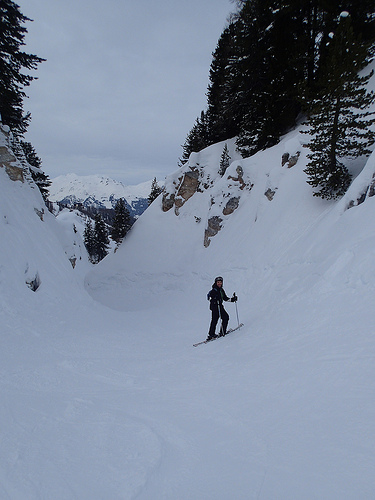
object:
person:
[207, 277, 238, 340]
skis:
[193, 323, 244, 347]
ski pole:
[217, 301, 225, 336]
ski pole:
[232, 292, 239, 330]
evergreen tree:
[111, 198, 132, 243]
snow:
[0, 60, 374, 499]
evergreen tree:
[300, 43, 375, 199]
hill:
[86, 54, 375, 312]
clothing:
[207, 283, 232, 340]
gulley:
[24, 152, 195, 360]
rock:
[161, 169, 199, 215]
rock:
[203, 165, 253, 249]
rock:
[280, 150, 290, 166]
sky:
[13, 1, 243, 187]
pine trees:
[207, 1, 375, 160]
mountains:
[46, 172, 168, 213]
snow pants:
[208, 305, 229, 340]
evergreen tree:
[93, 210, 110, 260]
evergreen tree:
[83, 219, 96, 258]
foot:
[208, 334, 219, 341]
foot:
[218, 331, 228, 337]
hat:
[215, 276, 223, 284]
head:
[215, 276, 223, 288]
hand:
[230, 296, 238, 302]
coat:
[207, 284, 233, 310]